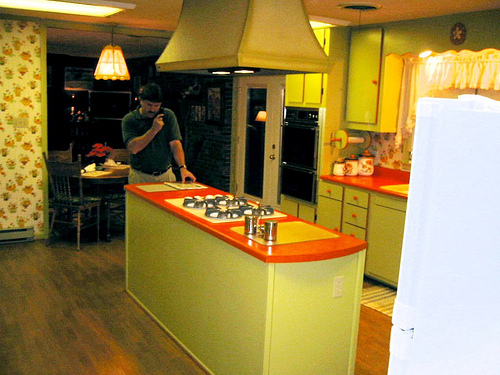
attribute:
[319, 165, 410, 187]
counter — orange 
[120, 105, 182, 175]
shirt — green 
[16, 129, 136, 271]
chair — wooden 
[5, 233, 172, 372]
floor — brown 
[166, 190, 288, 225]
stove — gas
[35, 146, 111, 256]
chair — brown 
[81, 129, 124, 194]
flowers — red 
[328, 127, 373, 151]
holder — empty 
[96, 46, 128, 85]
lights — on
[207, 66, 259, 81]
lights — on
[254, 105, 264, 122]
lights — on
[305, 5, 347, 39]
lights — on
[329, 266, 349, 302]
outlet — white 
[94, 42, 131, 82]
lamp shade — hanging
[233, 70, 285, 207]
whiteb backdoor — white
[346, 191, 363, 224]
knob — red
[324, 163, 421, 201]
counter — red 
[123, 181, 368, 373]
island counter — long 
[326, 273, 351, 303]
outlet — white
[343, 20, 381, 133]
cabinet — green 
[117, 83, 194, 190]
man — talking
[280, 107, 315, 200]
double oven — black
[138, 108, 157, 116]
mustache — black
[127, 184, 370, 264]
counter — orange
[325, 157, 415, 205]
counter — orange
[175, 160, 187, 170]
wristwatch — black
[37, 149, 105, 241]
kitchen chair — brown